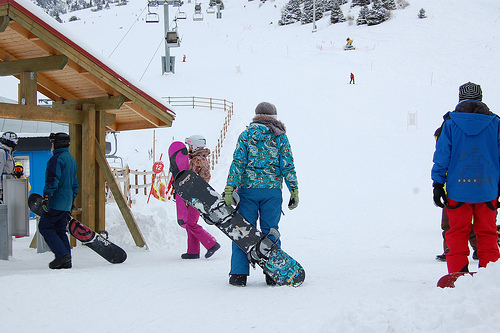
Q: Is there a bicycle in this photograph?
A: No, there are no bicycles.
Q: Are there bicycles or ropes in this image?
A: No, there are no bicycles or ropes.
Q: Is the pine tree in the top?
A: Yes, the pine tree is in the top of the image.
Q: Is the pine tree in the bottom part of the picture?
A: No, the pine tree is in the top of the image.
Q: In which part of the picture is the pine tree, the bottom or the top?
A: The pine tree is in the top of the image.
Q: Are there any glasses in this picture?
A: No, there are no glasses.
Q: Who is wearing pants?
A: The man is wearing pants.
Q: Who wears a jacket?
A: The man wears a jacket.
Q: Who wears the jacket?
A: The man wears a jacket.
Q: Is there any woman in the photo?
A: Yes, there is a woman.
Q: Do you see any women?
A: Yes, there is a woman.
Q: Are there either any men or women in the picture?
A: Yes, there is a woman.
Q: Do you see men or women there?
A: Yes, there is a woman.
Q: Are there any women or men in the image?
A: Yes, there is a woman.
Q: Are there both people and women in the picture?
A: Yes, there are both a woman and a person.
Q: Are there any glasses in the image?
A: No, there are no glasses.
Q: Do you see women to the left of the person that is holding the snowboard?
A: Yes, there is a woman to the left of the person.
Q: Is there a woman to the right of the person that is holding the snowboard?
A: No, the woman is to the left of the person.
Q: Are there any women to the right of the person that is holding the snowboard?
A: No, the woman is to the left of the person.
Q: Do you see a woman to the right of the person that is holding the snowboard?
A: No, the woman is to the left of the person.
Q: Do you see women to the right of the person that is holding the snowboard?
A: No, the woman is to the left of the person.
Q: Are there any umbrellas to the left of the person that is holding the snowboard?
A: No, there is a woman to the left of the person.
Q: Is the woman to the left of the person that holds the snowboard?
A: Yes, the woman is to the left of the person.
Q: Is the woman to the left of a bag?
A: No, the woman is to the left of the person.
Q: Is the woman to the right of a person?
A: No, the woman is to the left of a person.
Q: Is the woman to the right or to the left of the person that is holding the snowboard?
A: The woman is to the left of the person.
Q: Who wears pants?
A: The woman wears pants.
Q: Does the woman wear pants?
A: Yes, the woman wears pants.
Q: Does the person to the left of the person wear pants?
A: Yes, the woman wears pants.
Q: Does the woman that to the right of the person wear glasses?
A: No, the woman wears pants.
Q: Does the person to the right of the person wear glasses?
A: No, the woman wears pants.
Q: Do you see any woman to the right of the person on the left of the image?
A: Yes, there is a woman to the right of the person.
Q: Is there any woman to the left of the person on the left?
A: No, the woman is to the right of the person.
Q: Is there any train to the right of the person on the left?
A: No, there is a woman to the right of the person.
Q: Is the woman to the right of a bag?
A: No, the woman is to the right of a person.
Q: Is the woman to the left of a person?
A: No, the woman is to the right of a person.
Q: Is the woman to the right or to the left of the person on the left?
A: The woman is to the right of the person.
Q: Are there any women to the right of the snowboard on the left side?
A: Yes, there is a woman to the right of the snowboard.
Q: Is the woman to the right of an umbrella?
A: No, the woman is to the right of the snowboard.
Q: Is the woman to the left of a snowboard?
A: No, the woman is to the right of a snowboard.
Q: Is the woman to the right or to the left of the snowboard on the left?
A: The woman is to the right of the snowboard.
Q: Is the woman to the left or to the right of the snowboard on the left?
A: The woman is to the right of the snowboard.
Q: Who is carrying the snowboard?
A: The woman is carrying the snowboard.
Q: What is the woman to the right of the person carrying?
A: The woman is carrying a snowboard.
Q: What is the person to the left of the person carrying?
A: The woman is carrying a snowboard.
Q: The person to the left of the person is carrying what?
A: The woman is carrying a snowboard.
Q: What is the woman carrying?
A: The woman is carrying a snowboard.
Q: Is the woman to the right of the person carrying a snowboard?
A: Yes, the woman is carrying a snowboard.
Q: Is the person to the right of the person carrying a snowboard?
A: Yes, the woman is carrying a snowboard.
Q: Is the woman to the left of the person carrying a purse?
A: No, the woman is carrying a snowboard.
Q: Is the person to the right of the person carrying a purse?
A: No, the woman is carrying a snowboard.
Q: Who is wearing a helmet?
A: The woman is wearing a helmet.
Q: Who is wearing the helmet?
A: The woman is wearing a helmet.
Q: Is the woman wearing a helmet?
A: Yes, the woman is wearing a helmet.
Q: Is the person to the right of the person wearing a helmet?
A: Yes, the woman is wearing a helmet.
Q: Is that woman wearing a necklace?
A: No, the woman is wearing a helmet.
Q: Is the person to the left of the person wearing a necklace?
A: No, the woman is wearing a helmet.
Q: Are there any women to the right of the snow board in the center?
A: Yes, there is a woman to the right of the snowboard.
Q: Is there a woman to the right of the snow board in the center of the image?
A: Yes, there is a woman to the right of the snowboard.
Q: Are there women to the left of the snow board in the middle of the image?
A: No, the woman is to the right of the snowboard.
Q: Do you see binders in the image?
A: No, there are no binders.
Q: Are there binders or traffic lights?
A: No, there are no binders or traffic lights.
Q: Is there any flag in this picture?
A: No, there are no flags.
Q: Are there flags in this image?
A: No, there are no flags.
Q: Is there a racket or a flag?
A: No, there are no flags or rackets.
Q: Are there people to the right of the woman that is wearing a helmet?
A: Yes, there is a person to the right of the woman.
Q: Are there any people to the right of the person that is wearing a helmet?
A: Yes, there is a person to the right of the woman.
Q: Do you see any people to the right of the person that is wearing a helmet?
A: Yes, there is a person to the right of the woman.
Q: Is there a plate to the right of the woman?
A: No, there is a person to the right of the woman.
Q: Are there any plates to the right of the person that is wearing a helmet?
A: No, there is a person to the right of the woman.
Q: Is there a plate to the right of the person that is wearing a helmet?
A: No, there is a person to the right of the woman.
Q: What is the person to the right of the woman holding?
A: The person is holding the snow board.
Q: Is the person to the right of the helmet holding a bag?
A: No, the person is holding the snow board.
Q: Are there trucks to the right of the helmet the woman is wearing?
A: No, there is a person to the right of the helmet.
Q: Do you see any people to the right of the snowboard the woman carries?
A: Yes, there is a person to the right of the snowboard.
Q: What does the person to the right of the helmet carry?
A: The person carries a snowboard.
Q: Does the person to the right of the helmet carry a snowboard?
A: Yes, the person carries a snowboard.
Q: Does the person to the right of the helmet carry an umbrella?
A: No, the person carries a snowboard.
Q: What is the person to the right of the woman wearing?
A: The person is wearing an outfit.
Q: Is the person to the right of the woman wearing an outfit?
A: Yes, the person is wearing an outfit.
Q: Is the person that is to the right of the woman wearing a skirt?
A: No, the person is wearing an outfit.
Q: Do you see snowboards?
A: Yes, there is a snowboard.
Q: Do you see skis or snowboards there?
A: Yes, there is a snowboard.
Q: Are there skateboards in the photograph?
A: No, there are no skateboards.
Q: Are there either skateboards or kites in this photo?
A: No, there are no skateboards or kites.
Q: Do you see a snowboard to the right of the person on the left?
A: Yes, there is a snowboard to the right of the person.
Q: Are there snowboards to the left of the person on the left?
A: No, the snowboard is to the right of the person.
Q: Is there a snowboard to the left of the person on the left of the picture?
A: No, the snowboard is to the right of the person.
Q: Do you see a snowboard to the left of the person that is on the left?
A: No, the snowboard is to the right of the person.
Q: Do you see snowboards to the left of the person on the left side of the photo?
A: No, the snowboard is to the right of the person.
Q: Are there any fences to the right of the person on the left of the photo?
A: No, there is a snowboard to the right of the person.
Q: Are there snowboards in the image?
A: Yes, there is a snowboard.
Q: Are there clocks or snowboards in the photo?
A: Yes, there is a snowboard.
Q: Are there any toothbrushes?
A: No, there are no toothbrushes.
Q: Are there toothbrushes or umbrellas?
A: No, there are no toothbrushes or umbrellas.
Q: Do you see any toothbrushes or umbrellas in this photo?
A: No, there are no toothbrushes or umbrellas.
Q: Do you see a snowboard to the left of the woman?
A: Yes, there is a snowboard to the left of the woman.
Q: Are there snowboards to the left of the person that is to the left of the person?
A: Yes, there is a snowboard to the left of the woman.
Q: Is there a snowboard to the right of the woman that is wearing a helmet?
A: No, the snowboard is to the left of the woman.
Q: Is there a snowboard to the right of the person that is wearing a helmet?
A: No, the snowboard is to the left of the woman.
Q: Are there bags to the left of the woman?
A: No, there is a snowboard to the left of the woman.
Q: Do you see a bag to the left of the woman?
A: No, there is a snowboard to the left of the woman.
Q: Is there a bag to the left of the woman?
A: No, there is a snowboard to the left of the woman.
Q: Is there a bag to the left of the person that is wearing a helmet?
A: No, there is a snowboard to the left of the woman.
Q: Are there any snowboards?
A: Yes, there is a snowboard.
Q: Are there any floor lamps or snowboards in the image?
A: Yes, there is a snowboard.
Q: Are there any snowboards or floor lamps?
A: Yes, there is a snowboard.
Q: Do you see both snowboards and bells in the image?
A: No, there is a snowboard but no bells.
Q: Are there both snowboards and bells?
A: No, there is a snowboard but no bells.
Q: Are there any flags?
A: No, there are no flags.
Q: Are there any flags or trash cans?
A: No, there are no flags or trash cans.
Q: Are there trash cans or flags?
A: No, there are no flags or trash cans.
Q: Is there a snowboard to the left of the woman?
A: Yes, there is a snowboard to the left of the woman.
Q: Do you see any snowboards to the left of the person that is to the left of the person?
A: Yes, there is a snowboard to the left of the woman.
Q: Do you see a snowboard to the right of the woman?
A: No, the snowboard is to the left of the woman.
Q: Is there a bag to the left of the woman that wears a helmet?
A: No, there is a snowboard to the left of the woman.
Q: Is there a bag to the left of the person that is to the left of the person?
A: No, there is a snowboard to the left of the woman.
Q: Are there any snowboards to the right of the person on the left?
A: Yes, there is a snowboard to the right of the person.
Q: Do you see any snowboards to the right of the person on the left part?
A: Yes, there is a snowboard to the right of the person.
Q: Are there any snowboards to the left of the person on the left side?
A: No, the snowboard is to the right of the person.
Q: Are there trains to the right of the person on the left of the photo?
A: No, there is a snowboard to the right of the person.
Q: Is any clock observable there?
A: No, there are no clocks.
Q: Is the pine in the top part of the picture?
A: Yes, the pine is in the top of the image.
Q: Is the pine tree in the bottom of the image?
A: No, the pine tree is in the top of the image.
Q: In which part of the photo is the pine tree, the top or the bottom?
A: The pine tree is in the top of the image.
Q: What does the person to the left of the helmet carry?
A: The person carries a snowboard.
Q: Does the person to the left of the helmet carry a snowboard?
A: Yes, the person carries a snowboard.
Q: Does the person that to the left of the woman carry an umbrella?
A: No, the person carries a snowboard.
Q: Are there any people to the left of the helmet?
A: Yes, there is a person to the left of the helmet.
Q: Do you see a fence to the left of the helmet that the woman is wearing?
A: No, there is a person to the left of the helmet.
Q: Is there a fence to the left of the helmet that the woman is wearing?
A: No, there is a person to the left of the helmet.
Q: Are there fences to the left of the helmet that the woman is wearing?
A: No, there is a person to the left of the helmet.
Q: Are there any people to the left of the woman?
A: Yes, there is a person to the left of the woman.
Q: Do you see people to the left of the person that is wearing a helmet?
A: Yes, there is a person to the left of the woman.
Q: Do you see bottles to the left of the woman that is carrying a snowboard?
A: No, there is a person to the left of the woman.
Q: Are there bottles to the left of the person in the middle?
A: No, there is a person to the left of the woman.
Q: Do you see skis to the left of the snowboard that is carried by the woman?
A: No, there is a person to the left of the snowboard.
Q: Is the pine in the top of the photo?
A: Yes, the pine is in the top of the image.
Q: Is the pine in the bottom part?
A: No, the pine is in the top of the image.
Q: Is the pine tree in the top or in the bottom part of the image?
A: The pine tree is in the top of the image.